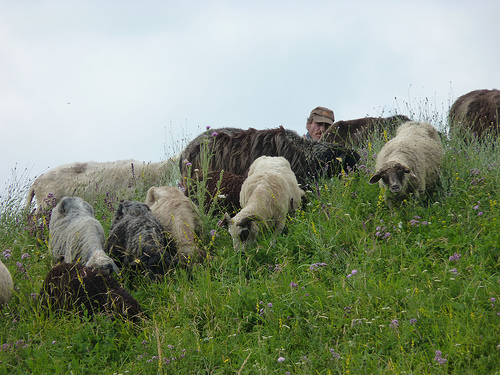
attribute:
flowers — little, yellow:
[289, 171, 384, 268]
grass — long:
[287, 132, 379, 265]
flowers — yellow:
[306, 219, 322, 235]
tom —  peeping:
[301, 104, 334, 144]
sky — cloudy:
[16, 14, 496, 120]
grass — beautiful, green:
[315, 236, 495, 369]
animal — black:
[24, 262, 150, 329]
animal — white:
[21, 157, 173, 223]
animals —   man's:
[28, 160, 300, 321]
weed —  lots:
[446, 252, 458, 284]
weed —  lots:
[428, 342, 450, 370]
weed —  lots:
[471, 201, 481, 214]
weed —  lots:
[375, 222, 386, 242]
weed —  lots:
[300, 262, 322, 276]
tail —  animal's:
[19, 180, 36, 223]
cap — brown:
[308, 105, 337, 127]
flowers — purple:
[273, 248, 477, 370]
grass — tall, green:
[303, 211, 475, 358]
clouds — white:
[45, 14, 370, 120]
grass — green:
[189, 241, 489, 371]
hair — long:
[184, 113, 337, 185]